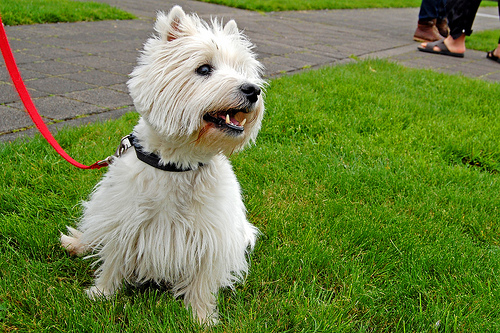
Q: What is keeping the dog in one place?
A: The red leash.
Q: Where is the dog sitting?
A: The grass.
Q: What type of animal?
A: Dog.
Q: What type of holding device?
A: Leash.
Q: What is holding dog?
A: Leash.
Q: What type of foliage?
A: Grass.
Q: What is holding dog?
A: Leash.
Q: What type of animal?
A: Dog.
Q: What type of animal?
A: Dog.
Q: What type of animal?
A: Dog.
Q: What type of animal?
A: Dog.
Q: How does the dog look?
A: Curious.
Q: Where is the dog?
A: On the grass.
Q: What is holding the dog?
A: A leash.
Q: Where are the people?
A: On the sidewalk.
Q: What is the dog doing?
A: Looking.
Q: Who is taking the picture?
A: The owner of the dog.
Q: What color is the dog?
A: White.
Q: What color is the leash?
A: Red.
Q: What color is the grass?
A: Green.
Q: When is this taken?
A: Daytime.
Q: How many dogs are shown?
A: 1.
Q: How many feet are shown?
A: 4.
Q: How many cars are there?
A: 0.